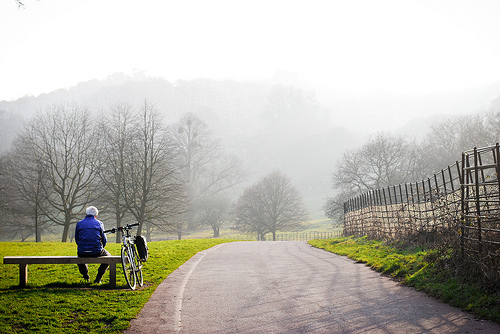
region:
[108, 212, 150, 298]
bicycle leaning against a bench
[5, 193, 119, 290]
elderly man sitting on bench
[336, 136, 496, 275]
fence on the side of the road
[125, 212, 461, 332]
curved one lane road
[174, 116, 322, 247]
trees in the fog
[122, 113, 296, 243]
the trees are leaf less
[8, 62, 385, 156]
mountains on the horizon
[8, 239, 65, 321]
bench on green grass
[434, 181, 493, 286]
vines on a fence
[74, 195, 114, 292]
elderly man in blue coat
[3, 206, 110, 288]
a man sitting on a park bench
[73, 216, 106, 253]
the man is wearing a blue and purple jacket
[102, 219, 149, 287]
a bicycle is leaning against the bench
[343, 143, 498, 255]
a fence along the road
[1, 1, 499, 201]
a foggy area ahead of the road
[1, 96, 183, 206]
deciduous trees in front of the man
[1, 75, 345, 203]
a hill behind the trees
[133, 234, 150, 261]
a side saddle bag on the bike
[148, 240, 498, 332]
a paved asphalt street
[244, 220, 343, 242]
a fence on the opposite side of the road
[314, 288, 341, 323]
Cracks in the pavement.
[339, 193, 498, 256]
A fence in the grass.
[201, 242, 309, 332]
A grey cement road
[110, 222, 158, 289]
A bicycle leans upright.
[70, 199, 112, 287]
A man sits down.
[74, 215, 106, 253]
A blue mans jacket.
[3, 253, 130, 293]
A cement bench on the grass.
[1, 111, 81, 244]
Trees with no leaves.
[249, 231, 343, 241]
A fence along the road.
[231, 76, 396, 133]
An overcast cloudy sky.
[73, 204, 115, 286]
man sitting on bench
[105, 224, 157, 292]
bicycle leaning on bench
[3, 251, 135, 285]
grey stone backless bench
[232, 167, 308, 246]
large tree with no leaves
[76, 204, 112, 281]
man wearing blue jacket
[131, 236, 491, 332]
asphalt path in park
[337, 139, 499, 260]
wooden fence by path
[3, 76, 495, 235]
light fog over park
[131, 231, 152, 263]
black backpack on bike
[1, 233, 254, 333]
green grass in park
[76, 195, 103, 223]
Person has white hair.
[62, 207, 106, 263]
Person wearing blue coat.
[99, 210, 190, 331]
Bike leaning against bench.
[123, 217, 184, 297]
Dark bag attached to bike.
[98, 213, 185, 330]
Bike is a mountain bike.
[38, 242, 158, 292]
Person is wearing dark pants.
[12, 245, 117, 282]
Bench is concrete.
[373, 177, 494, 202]
Fence on right side of road.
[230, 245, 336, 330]
Pavement is gray on path.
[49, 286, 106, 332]
Grass is green on ground.